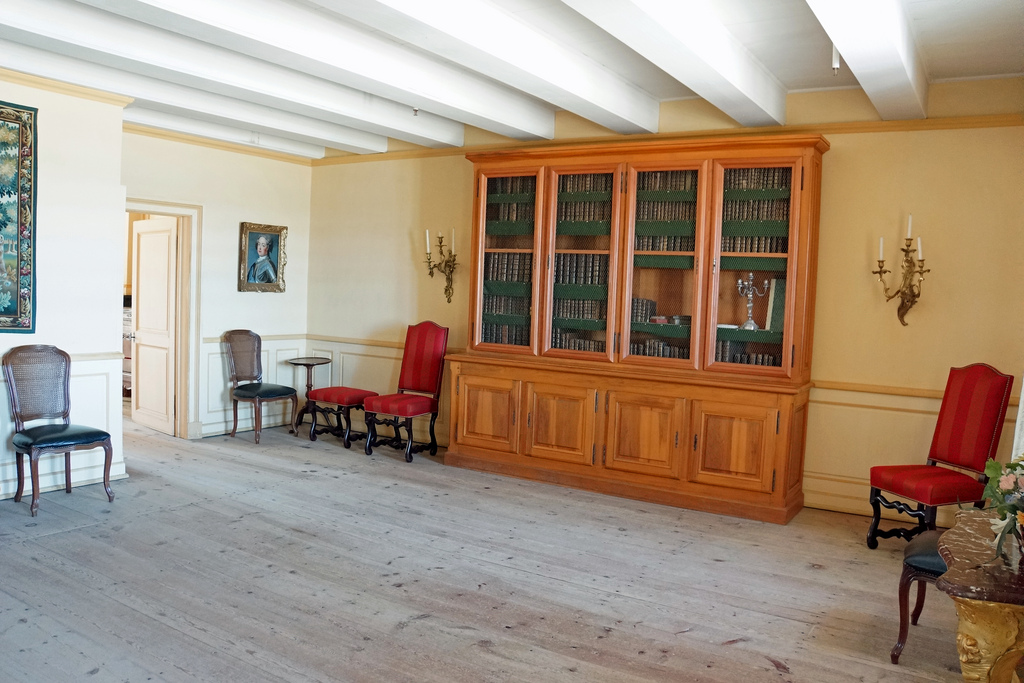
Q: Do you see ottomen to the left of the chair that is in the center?
A: Yes, there is an ottoman to the left of the chair.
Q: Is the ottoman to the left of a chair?
A: Yes, the ottoman is to the left of a chair.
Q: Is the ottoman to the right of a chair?
A: No, the ottoman is to the left of a chair.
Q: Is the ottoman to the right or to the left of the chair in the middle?
A: The ottoman is to the left of the chair.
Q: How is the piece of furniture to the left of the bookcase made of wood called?
A: The piece of furniture is an ottoman.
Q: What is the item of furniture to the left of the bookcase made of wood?
A: The piece of furniture is an ottoman.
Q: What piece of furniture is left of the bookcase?
A: The piece of furniture is an ottoman.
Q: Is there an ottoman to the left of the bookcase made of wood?
A: Yes, there is an ottoman to the left of the bookcase.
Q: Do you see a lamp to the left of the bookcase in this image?
A: No, there is an ottoman to the left of the bookcase.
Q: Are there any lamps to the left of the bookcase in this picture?
A: No, there is an ottoman to the left of the bookcase.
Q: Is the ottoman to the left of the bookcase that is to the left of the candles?
A: Yes, the ottoman is to the left of the bookcase.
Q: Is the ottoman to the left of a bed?
A: No, the ottoman is to the left of the bookcase.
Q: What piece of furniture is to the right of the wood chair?
A: The piece of furniture is an ottoman.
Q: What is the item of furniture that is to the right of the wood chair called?
A: The piece of furniture is an ottoman.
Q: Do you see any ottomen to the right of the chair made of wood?
A: Yes, there is an ottoman to the right of the chair.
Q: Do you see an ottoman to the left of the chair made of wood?
A: No, the ottoman is to the right of the chair.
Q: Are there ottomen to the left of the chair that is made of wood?
A: No, the ottoman is to the right of the chair.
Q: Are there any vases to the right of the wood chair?
A: No, there is an ottoman to the right of the chair.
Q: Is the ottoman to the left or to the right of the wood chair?
A: The ottoman is to the right of the chair.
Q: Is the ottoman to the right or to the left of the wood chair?
A: The ottoman is to the right of the chair.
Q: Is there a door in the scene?
A: Yes, there is a door.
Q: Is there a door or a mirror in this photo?
A: Yes, there is a door.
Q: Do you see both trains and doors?
A: No, there is a door but no trains.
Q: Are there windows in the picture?
A: No, there are no windows.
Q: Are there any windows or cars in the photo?
A: No, there are no windows or cars.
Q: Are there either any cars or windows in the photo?
A: No, there are no windows or cars.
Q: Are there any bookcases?
A: Yes, there is a bookcase.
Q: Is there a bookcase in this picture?
A: Yes, there is a bookcase.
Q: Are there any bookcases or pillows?
A: Yes, there is a bookcase.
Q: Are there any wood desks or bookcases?
A: Yes, there is a wood bookcase.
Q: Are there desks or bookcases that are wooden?
A: Yes, the bookcase is wooden.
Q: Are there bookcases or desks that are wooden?
A: Yes, the bookcase is wooden.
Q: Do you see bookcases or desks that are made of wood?
A: Yes, the bookcase is made of wood.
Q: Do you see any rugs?
A: No, there are no rugs.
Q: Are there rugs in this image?
A: No, there are no rugs.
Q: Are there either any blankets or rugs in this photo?
A: No, there are no rugs or blankets.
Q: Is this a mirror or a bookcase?
A: This is a bookcase.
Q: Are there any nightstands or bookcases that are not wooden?
A: No, there is a bookcase but it is wooden.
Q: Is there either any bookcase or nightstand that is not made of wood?
A: No, there is a bookcase but it is made of wood.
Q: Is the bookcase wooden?
A: Yes, the bookcase is wooden.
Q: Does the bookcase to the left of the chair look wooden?
A: Yes, the bookcase is wooden.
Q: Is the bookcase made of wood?
A: Yes, the bookcase is made of wood.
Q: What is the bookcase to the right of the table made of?
A: The bookcase is made of wood.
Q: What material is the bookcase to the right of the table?
A: The bookcase is made of wood.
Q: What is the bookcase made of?
A: The bookcase is made of wood.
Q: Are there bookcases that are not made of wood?
A: No, there is a bookcase but it is made of wood.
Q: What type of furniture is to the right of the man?
A: The piece of furniture is a bookcase.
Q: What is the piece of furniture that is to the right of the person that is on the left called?
A: The piece of furniture is a bookcase.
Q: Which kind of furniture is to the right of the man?
A: The piece of furniture is a bookcase.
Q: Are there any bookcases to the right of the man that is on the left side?
A: Yes, there is a bookcase to the right of the man.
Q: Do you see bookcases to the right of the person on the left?
A: Yes, there is a bookcase to the right of the man.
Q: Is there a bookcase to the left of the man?
A: No, the bookcase is to the right of the man.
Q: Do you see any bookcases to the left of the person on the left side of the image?
A: No, the bookcase is to the right of the man.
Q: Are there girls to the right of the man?
A: No, there is a bookcase to the right of the man.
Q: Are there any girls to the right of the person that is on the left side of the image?
A: No, there is a bookcase to the right of the man.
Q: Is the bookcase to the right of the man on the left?
A: Yes, the bookcase is to the right of the man.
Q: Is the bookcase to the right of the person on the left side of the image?
A: Yes, the bookcase is to the right of the man.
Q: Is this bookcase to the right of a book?
A: No, the bookcase is to the right of the man.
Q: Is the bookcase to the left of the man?
A: No, the bookcase is to the right of the man.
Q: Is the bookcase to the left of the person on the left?
A: No, the bookcase is to the right of the man.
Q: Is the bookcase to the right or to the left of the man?
A: The bookcase is to the right of the man.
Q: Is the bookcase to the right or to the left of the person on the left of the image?
A: The bookcase is to the right of the man.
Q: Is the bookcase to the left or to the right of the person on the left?
A: The bookcase is to the right of the man.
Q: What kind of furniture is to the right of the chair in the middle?
A: The piece of furniture is a bookcase.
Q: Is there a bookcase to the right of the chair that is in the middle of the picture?
A: Yes, there is a bookcase to the right of the chair.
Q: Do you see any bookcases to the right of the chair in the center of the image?
A: Yes, there is a bookcase to the right of the chair.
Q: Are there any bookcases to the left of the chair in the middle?
A: No, the bookcase is to the right of the chair.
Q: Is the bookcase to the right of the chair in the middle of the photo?
A: Yes, the bookcase is to the right of the chair.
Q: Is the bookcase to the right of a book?
A: No, the bookcase is to the right of the chair.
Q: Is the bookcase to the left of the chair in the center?
A: No, the bookcase is to the right of the chair.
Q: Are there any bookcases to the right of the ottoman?
A: Yes, there is a bookcase to the right of the ottoman.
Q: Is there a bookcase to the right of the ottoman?
A: Yes, there is a bookcase to the right of the ottoman.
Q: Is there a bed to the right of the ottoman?
A: No, there is a bookcase to the right of the ottoman.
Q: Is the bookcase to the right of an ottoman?
A: Yes, the bookcase is to the right of an ottoman.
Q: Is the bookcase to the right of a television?
A: No, the bookcase is to the right of an ottoman.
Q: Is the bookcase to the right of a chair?
A: Yes, the bookcase is to the right of a chair.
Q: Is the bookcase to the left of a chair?
A: No, the bookcase is to the right of a chair.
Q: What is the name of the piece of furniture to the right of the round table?
A: The piece of furniture is a bookcase.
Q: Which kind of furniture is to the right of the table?
A: The piece of furniture is a bookcase.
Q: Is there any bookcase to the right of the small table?
A: Yes, there is a bookcase to the right of the table.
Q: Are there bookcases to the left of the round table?
A: No, the bookcase is to the right of the table.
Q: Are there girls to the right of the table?
A: No, there is a bookcase to the right of the table.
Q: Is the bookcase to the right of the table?
A: Yes, the bookcase is to the right of the table.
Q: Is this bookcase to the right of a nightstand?
A: No, the bookcase is to the right of the table.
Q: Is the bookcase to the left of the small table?
A: No, the bookcase is to the right of the table.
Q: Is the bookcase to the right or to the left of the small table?
A: The bookcase is to the right of the table.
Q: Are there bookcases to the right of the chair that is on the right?
A: No, the bookcase is to the left of the chair.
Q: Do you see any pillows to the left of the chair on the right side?
A: No, there is a bookcase to the left of the chair.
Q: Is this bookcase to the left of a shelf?
A: No, the bookcase is to the left of a chair.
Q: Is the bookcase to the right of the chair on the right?
A: No, the bookcase is to the left of the chair.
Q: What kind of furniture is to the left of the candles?
A: The piece of furniture is a bookcase.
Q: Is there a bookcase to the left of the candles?
A: Yes, there is a bookcase to the left of the candles.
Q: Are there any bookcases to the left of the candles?
A: Yes, there is a bookcase to the left of the candles.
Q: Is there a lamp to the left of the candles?
A: No, there is a bookcase to the left of the candles.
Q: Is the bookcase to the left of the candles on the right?
A: Yes, the bookcase is to the left of the candles.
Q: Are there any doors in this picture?
A: Yes, there are doors.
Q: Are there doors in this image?
A: Yes, there are doors.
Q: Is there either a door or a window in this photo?
A: Yes, there are doors.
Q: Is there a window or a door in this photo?
A: Yes, there are doors.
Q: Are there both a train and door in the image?
A: No, there are doors but no trains.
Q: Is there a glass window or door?
A: Yes, there are glass doors.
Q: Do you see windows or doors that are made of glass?
A: Yes, the doors are made of glass.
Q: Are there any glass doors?
A: Yes, there are doors that are made of glass.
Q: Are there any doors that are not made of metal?
A: Yes, there are doors that are made of glass.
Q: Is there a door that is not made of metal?
A: Yes, there are doors that are made of glass.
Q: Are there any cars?
A: No, there are no cars.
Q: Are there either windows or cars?
A: No, there are no cars or windows.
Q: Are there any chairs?
A: Yes, there is a chair.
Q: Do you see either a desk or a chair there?
A: Yes, there is a chair.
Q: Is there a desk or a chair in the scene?
A: Yes, there is a chair.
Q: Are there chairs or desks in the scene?
A: Yes, there is a chair.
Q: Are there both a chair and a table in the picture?
A: Yes, there are both a chair and a table.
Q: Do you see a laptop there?
A: No, there are no laptops.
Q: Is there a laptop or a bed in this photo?
A: No, there are no laptops or beds.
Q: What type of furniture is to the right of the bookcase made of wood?
A: The piece of furniture is a chair.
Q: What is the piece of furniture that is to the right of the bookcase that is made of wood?
A: The piece of furniture is a chair.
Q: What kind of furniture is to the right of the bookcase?
A: The piece of furniture is a chair.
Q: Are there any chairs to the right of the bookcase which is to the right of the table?
A: Yes, there is a chair to the right of the bookcase.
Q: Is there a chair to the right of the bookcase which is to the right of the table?
A: Yes, there is a chair to the right of the bookcase.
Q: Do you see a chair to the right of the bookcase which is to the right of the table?
A: Yes, there is a chair to the right of the bookcase.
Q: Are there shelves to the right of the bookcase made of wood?
A: No, there is a chair to the right of the bookcase.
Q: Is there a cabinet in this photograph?
A: Yes, there is a cabinet.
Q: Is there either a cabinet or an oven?
A: Yes, there is a cabinet.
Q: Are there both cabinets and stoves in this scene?
A: No, there is a cabinet but no stoves.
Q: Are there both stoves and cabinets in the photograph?
A: No, there is a cabinet but no stoves.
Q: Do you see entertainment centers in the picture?
A: No, there are no entertainment centers.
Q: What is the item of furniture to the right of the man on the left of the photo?
A: The piece of furniture is a cabinet.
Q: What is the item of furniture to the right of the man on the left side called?
A: The piece of furniture is a cabinet.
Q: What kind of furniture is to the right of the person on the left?
A: The piece of furniture is a cabinet.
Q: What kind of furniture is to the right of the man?
A: The piece of furniture is a cabinet.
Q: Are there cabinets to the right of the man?
A: Yes, there is a cabinet to the right of the man.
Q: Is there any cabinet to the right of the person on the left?
A: Yes, there is a cabinet to the right of the man.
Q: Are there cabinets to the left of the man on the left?
A: No, the cabinet is to the right of the man.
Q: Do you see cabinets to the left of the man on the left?
A: No, the cabinet is to the right of the man.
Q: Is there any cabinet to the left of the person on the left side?
A: No, the cabinet is to the right of the man.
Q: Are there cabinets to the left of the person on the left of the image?
A: No, the cabinet is to the right of the man.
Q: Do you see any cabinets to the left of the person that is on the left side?
A: No, the cabinet is to the right of the man.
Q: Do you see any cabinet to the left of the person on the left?
A: No, the cabinet is to the right of the man.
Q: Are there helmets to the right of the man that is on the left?
A: No, there is a cabinet to the right of the man.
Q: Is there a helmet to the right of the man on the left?
A: No, there is a cabinet to the right of the man.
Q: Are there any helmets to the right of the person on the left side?
A: No, there is a cabinet to the right of the man.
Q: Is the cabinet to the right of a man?
A: Yes, the cabinet is to the right of a man.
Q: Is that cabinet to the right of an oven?
A: No, the cabinet is to the right of a man.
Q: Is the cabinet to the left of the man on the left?
A: No, the cabinet is to the right of the man.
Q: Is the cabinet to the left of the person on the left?
A: No, the cabinet is to the right of the man.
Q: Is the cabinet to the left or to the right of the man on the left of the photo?
A: The cabinet is to the right of the man.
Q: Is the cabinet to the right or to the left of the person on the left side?
A: The cabinet is to the right of the man.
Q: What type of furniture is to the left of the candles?
A: The piece of furniture is a cabinet.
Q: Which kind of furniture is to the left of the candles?
A: The piece of furniture is a cabinet.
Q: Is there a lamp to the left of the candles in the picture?
A: No, there is a cabinet to the left of the candles.